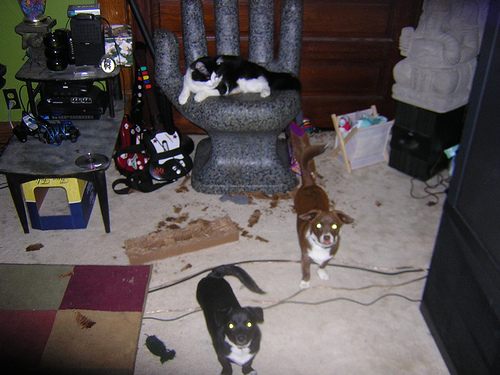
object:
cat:
[178, 54, 303, 106]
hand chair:
[152, 0, 305, 197]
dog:
[293, 143, 355, 289]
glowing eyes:
[316, 223, 323, 230]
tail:
[297, 141, 329, 186]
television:
[419, 0, 500, 374]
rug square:
[58, 264, 152, 312]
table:
[0, 88, 129, 233]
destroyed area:
[149, 167, 335, 246]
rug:
[0, 261, 153, 375]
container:
[329, 104, 395, 174]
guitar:
[130, 46, 196, 181]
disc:
[75, 152, 111, 171]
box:
[21, 177, 97, 231]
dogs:
[195, 263, 267, 374]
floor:
[0, 130, 456, 375]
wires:
[144, 257, 432, 295]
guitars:
[110, 41, 154, 178]